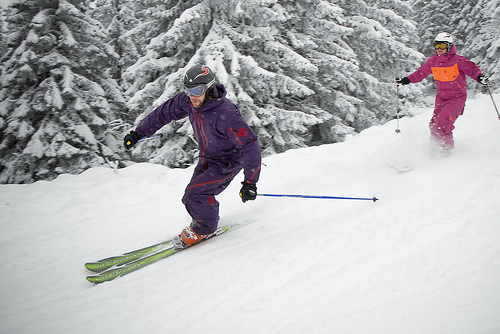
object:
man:
[123, 64, 262, 251]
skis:
[84, 224, 236, 283]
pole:
[239, 193, 379, 202]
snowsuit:
[403, 32, 481, 153]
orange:
[436, 68, 444, 78]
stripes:
[187, 173, 232, 190]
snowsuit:
[133, 64, 262, 237]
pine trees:
[0, 0, 123, 185]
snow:
[0, 0, 497, 334]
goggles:
[434, 43, 448, 49]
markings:
[194, 65, 210, 83]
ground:
[0, 91, 499, 333]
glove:
[239, 182, 258, 203]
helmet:
[183, 65, 220, 95]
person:
[391, 31, 490, 161]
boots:
[173, 230, 220, 251]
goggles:
[181, 85, 210, 97]